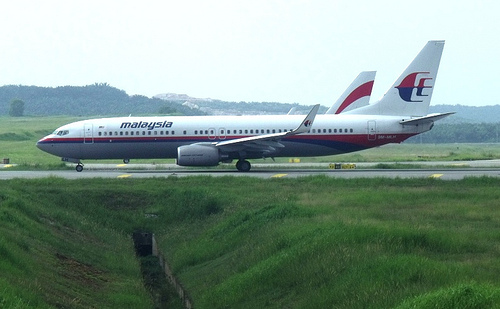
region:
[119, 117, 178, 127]
The word on the side of the plane is in black.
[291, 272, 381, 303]
The grass is green in color.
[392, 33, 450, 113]
The tail red white and blue.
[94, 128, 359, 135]
There are many windows on the side of the plane.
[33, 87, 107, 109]
The trees in the background are green.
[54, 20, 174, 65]
The sky is clear.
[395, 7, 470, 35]
The sky is blue.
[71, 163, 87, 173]
The front wheel is black.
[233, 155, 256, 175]
The back wheel is black.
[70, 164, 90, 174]
The front wheel is round.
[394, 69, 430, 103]
a blue and red plane logo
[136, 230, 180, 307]
an irrigation ditch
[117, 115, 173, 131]
a company name on a plane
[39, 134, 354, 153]
blue and red stripes on a plane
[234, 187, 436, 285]
thick green grass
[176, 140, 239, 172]
a large gray wing engine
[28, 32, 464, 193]
a plane coasting on the runway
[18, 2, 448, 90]
a cloudy white sky overhead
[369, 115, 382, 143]
an emergency door on the plane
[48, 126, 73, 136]
the cockpit window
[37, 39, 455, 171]
Jet airline on runway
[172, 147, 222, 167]
Jet engine on wing of airplane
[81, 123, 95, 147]
Front egress door on airplane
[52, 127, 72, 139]
Cockpit of jet airplane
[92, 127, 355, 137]
Passenger windows on airplane fuselage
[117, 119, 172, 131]
Airline owner identification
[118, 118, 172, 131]
Malaysia painted on side of airplane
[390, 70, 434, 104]
Malaysia air business logo on tail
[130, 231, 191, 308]
Drainage ditch under runway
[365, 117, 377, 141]
Rear egress door on airplane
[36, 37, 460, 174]
Aircraft moving in the taxi way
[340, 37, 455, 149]
Tail section of the aircraft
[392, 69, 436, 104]
Airline logo on the tail of the aircraft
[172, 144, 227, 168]
engine of the airfract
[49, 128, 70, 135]
Cockpit glass on the aircraft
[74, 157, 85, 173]
Nose landing gear of the aircraft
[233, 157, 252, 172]
Main landing gear of the aircraft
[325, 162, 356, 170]
Taxi way indication near the aircraft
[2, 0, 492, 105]
Clear sky in the background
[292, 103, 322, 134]
Wingtip of the aircraft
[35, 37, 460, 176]
airplane on the runway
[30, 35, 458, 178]
Malaysia airplane on the runway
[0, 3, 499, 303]
airplane on the runway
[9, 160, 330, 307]
grassy ditch at the edge of runway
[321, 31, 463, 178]
tail of an airplane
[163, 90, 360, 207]
wing of an airplane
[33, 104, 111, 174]
cockpit of an airplane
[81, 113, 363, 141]
windows on an airplane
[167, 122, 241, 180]
engine of an airplane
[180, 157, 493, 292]
grassy area next to runway